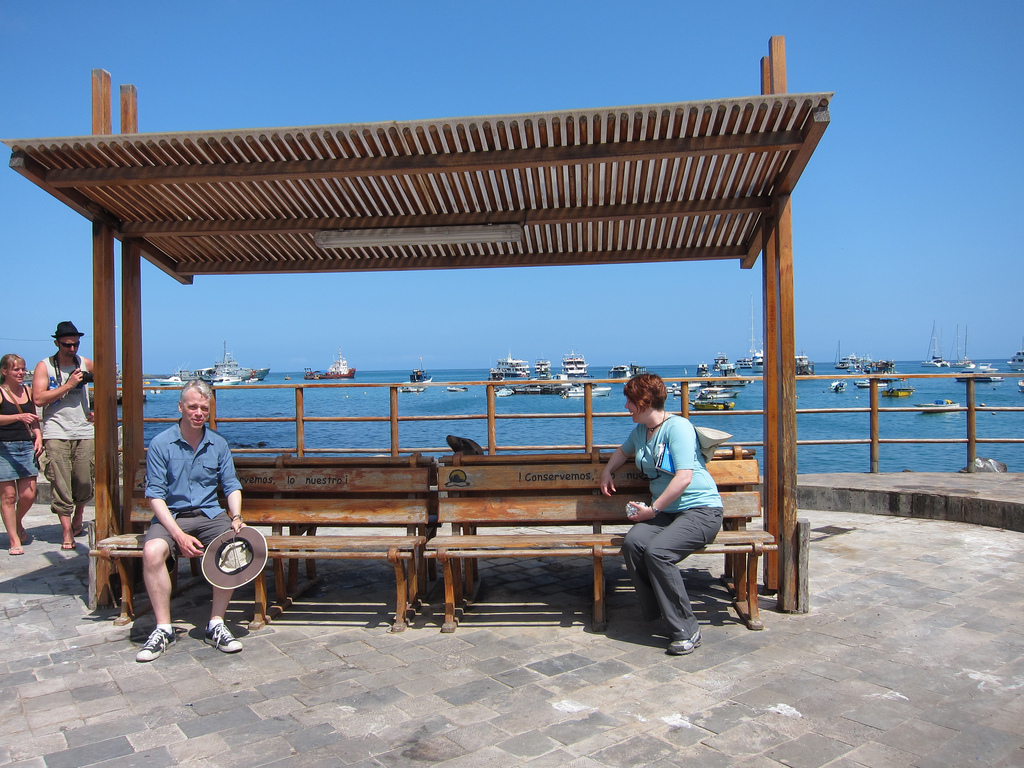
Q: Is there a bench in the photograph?
A: Yes, there is a bench.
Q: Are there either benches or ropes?
A: Yes, there is a bench.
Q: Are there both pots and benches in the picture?
A: No, there is a bench but no pots.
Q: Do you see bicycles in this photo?
A: No, there are no bicycles.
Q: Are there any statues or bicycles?
A: No, there are no bicycles or statues.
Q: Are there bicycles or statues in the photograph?
A: No, there are no bicycles or statues.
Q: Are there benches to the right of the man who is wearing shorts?
A: Yes, there is a bench to the right of the man.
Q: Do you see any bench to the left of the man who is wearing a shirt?
A: No, the bench is to the right of the man.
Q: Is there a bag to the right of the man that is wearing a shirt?
A: No, there is a bench to the right of the man.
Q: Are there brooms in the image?
A: No, there are no brooms.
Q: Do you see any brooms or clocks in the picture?
A: No, there are no brooms or clocks.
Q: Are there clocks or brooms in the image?
A: No, there are no brooms or clocks.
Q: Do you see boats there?
A: Yes, there is a boat.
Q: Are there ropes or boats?
A: Yes, there is a boat.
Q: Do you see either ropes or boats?
A: Yes, there is a boat.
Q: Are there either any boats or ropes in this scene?
A: Yes, there is a boat.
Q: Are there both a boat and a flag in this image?
A: No, there is a boat but no flags.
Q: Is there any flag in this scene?
A: No, there are no flags.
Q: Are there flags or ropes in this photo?
A: No, there are no flags or ropes.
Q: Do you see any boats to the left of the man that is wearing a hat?
A: No, the boat is to the right of the man.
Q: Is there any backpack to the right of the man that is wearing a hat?
A: No, there is a boat to the right of the man.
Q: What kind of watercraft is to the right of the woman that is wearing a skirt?
A: The watercraft is a boat.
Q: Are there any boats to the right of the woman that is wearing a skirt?
A: Yes, there is a boat to the right of the woman.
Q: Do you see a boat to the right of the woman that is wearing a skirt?
A: Yes, there is a boat to the right of the woman.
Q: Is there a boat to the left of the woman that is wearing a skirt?
A: No, the boat is to the right of the woman.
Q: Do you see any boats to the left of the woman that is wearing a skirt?
A: No, the boat is to the right of the woman.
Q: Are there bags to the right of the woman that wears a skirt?
A: No, there is a boat to the right of the woman.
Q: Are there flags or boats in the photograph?
A: Yes, there is a boat.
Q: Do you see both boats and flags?
A: No, there is a boat but no flags.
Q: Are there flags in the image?
A: No, there are no flags.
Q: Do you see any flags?
A: No, there are no flags.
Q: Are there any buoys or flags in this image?
A: No, there are no flags or buoys.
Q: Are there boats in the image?
A: Yes, there is a boat.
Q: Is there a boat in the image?
A: Yes, there is a boat.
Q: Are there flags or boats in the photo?
A: Yes, there is a boat.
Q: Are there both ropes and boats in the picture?
A: No, there is a boat but no ropes.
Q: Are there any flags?
A: No, there are no flags.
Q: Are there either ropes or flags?
A: No, there are no flags or ropes.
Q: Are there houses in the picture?
A: No, there are no houses.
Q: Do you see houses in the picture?
A: No, there are no houses.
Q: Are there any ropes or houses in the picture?
A: No, there are no houses or ropes.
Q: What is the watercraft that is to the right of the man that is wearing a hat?
A: The watercraft is boats.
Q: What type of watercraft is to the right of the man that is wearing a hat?
A: The watercraft is boats.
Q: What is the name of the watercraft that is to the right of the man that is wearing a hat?
A: The watercraft is boats.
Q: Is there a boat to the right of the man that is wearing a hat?
A: Yes, there are boats to the right of the man.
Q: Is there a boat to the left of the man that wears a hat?
A: No, the boats are to the right of the man.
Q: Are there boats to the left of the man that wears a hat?
A: No, the boats are to the right of the man.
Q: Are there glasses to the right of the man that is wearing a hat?
A: No, there are boats to the right of the man.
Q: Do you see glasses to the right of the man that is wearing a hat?
A: No, there are boats to the right of the man.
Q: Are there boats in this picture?
A: Yes, there is a boat.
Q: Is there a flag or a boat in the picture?
A: Yes, there is a boat.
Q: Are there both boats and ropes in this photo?
A: No, there is a boat but no ropes.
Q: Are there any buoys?
A: No, there are no buoys.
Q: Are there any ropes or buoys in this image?
A: No, there are no buoys or ropes.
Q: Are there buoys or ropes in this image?
A: No, there are no buoys or ropes.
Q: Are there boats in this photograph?
A: Yes, there is a boat.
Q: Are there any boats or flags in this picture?
A: Yes, there is a boat.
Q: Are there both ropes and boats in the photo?
A: No, there is a boat but no ropes.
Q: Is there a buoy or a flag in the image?
A: No, there are no flags or buoys.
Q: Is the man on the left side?
A: Yes, the man is on the left of the image.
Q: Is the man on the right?
A: No, the man is on the left of the image.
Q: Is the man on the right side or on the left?
A: The man is on the left of the image.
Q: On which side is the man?
A: The man is on the left of the image.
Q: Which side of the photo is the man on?
A: The man is on the left of the image.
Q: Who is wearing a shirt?
A: The man is wearing a shirt.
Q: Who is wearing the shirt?
A: The man is wearing a shirt.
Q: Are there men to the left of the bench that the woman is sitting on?
A: Yes, there is a man to the left of the bench.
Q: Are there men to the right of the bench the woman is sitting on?
A: No, the man is to the left of the bench.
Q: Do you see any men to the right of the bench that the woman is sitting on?
A: No, the man is to the left of the bench.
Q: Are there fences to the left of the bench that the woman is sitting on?
A: No, there is a man to the left of the bench.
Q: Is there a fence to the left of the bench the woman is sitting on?
A: No, there is a man to the left of the bench.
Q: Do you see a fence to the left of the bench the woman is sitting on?
A: No, there is a man to the left of the bench.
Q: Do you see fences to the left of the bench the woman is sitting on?
A: No, there is a man to the left of the bench.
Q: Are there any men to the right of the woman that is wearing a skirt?
A: Yes, there is a man to the right of the woman.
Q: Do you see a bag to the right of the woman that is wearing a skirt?
A: No, there is a man to the right of the woman.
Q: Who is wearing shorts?
A: The man is wearing shorts.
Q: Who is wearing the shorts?
A: The man is wearing shorts.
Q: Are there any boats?
A: Yes, there is a boat.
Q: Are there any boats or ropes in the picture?
A: Yes, there is a boat.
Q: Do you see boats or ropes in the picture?
A: Yes, there is a boat.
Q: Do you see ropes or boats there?
A: Yes, there is a boat.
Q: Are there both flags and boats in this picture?
A: No, there is a boat but no flags.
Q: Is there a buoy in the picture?
A: No, there are no buoys.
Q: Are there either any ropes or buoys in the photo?
A: No, there are no buoys or ropes.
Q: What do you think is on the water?
A: The boat is on the water.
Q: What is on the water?
A: The boat is on the water.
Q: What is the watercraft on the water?
A: The watercraft is a boat.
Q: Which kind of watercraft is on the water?
A: The watercraft is a boat.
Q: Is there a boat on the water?
A: Yes, there is a boat on the water.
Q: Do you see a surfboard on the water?
A: No, there is a boat on the water.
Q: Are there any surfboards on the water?
A: No, there is a boat on the water.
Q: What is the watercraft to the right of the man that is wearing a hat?
A: The watercraft is a boat.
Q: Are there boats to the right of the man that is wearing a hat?
A: Yes, there is a boat to the right of the man.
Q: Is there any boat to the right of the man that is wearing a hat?
A: Yes, there is a boat to the right of the man.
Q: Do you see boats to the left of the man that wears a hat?
A: No, the boat is to the right of the man.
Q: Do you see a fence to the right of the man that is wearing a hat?
A: No, there is a boat to the right of the man.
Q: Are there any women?
A: Yes, there is a woman.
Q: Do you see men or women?
A: Yes, there is a woman.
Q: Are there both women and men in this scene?
A: Yes, there are both a woman and a man.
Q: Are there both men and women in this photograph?
A: Yes, there are both a woman and a man.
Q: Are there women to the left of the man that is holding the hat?
A: Yes, there is a woman to the left of the man.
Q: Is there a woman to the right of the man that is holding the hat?
A: No, the woman is to the left of the man.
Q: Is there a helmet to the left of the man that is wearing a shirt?
A: No, there is a woman to the left of the man.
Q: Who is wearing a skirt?
A: The woman is wearing a skirt.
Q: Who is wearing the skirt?
A: The woman is wearing a skirt.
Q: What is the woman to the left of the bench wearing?
A: The woman is wearing a skirt.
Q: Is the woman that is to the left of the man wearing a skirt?
A: Yes, the woman is wearing a skirt.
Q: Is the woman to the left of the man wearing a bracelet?
A: No, the woman is wearing a skirt.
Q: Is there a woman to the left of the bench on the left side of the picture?
A: Yes, there is a woman to the left of the bench.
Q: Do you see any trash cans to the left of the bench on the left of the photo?
A: No, there is a woman to the left of the bench.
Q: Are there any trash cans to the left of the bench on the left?
A: No, there is a woman to the left of the bench.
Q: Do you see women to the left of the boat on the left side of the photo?
A: Yes, there is a woman to the left of the boat.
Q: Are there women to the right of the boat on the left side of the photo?
A: No, the woman is to the left of the boat.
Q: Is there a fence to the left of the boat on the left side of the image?
A: No, there is a woman to the left of the boat.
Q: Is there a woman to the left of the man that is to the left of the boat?
A: Yes, there is a woman to the left of the man.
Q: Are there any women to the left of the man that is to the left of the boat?
A: Yes, there is a woman to the left of the man.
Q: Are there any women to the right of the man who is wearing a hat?
A: No, the woman is to the left of the man.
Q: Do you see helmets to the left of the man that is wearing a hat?
A: No, there is a woman to the left of the man.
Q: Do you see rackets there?
A: No, there are no rackets.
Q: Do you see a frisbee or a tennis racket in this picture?
A: No, there are no rackets or frisbees.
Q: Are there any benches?
A: Yes, there is a bench.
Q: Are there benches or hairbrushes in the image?
A: Yes, there is a bench.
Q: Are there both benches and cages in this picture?
A: No, there is a bench but no cages.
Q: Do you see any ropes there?
A: No, there are no ropes.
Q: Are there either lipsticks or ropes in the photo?
A: No, there are no ropes or lipsticks.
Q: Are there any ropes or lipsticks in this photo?
A: No, there are no ropes or lipsticks.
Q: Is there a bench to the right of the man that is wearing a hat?
A: Yes, there is a bench to the right of the man.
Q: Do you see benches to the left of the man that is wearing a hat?
A: No, the bench is to the right of the man.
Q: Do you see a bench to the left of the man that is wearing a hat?
A: No, the bench is to the right of the man.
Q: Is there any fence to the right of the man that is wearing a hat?
A: No, there is a bench to the right of the man.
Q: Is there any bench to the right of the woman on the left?
A: Yes, there is a bench to the right of the woman.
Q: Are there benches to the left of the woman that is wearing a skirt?
A: No, the bench is to the right of the woman.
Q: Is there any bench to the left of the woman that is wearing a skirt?
A: No, the bench is to the right of the woman.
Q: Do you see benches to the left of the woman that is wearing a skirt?
A: No, the bench is to the right of the woman.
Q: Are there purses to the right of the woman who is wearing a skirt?
A: No, there is a bench to the right of the woman.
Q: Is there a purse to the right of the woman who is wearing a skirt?
A: No, there is a bench to the right of the woman.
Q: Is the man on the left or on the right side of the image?
A: The man is on the left of the image.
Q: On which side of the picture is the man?
A: The man is on the left of the image.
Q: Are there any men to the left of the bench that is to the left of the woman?
A: Yes, there is a man to the left of the bench.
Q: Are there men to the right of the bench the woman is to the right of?
A: No, the man is to the left of the bench.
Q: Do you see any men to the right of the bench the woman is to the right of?
A: No, the man is to the left of the bench.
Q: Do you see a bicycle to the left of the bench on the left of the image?
A: No, there is a man to the left of the bench.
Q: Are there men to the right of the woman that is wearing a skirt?
A: Yes, there is a man to the right of the woman.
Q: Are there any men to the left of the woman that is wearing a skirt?
A: No, the man is to the right of the woman.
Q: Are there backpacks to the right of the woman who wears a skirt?
A: No, there is a man to the right of the woman.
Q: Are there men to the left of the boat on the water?
A: Yes, there is a man to the left of the boat.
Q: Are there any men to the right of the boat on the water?
A: No, the man is to the left of the boat.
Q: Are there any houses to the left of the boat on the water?
A: No, there is a man to the left of the boat.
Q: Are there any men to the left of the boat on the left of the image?
A: Yes, there is a man to the left of the boat.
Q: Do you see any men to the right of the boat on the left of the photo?
A: No, the man is to the left of the boat.